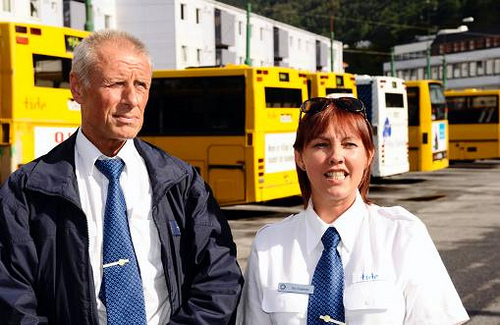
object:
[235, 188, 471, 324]
shirt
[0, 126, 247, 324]
black jacket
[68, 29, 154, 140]
head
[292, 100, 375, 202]
head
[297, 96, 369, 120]
glasses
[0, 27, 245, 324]
man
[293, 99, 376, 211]
hair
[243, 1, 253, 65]
pole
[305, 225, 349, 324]
blue tie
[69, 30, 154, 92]
gray hair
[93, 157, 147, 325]
ties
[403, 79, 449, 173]
buses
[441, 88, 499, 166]
buses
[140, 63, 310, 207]
buses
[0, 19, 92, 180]
buses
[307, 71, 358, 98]
buses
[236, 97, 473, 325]
person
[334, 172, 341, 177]
teeth